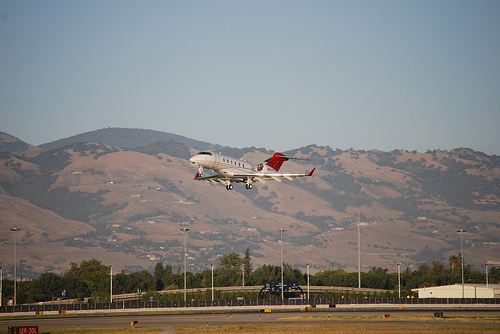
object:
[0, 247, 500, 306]
trees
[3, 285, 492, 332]
area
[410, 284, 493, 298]
home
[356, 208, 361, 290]
pole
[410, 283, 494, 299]
hangar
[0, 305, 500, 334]
ground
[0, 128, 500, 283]
mountains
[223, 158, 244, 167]
windows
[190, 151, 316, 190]
plane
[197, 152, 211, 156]
windows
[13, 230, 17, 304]
pole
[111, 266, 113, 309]
pole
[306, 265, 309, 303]
pole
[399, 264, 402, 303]
pole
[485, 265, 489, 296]
pole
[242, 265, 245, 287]
pole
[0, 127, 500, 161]
mountaintops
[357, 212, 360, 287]
pillars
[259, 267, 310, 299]
sign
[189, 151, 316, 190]
airplane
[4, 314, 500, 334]
grass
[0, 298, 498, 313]
fence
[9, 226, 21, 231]
light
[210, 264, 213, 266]
light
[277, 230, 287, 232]
light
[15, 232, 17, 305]
pole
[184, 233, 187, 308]
pole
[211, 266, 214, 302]
pole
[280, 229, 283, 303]
pole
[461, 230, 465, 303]
pole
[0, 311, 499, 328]
runway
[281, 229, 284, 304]
light pole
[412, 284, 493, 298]
structure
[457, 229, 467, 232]
light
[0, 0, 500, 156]
sky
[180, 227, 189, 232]
light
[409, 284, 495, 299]
building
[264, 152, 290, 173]
tail